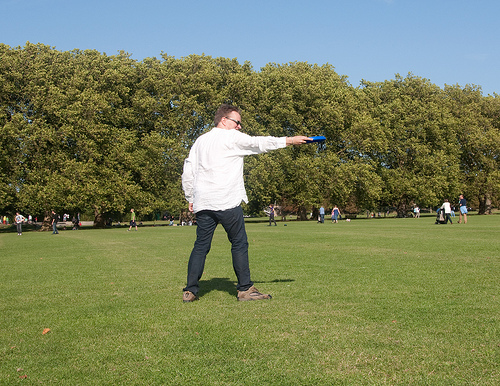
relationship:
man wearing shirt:
[165, 83, 329, 302] [180, 126, 288, 215]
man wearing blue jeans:
[165, 83, 329, 302] [178, 198, 262, 291]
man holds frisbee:
[180, 102, 315, 304] [302, 132, 327, 145]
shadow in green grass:
[190, 261, 293, 299] [0, 209, 499, 385]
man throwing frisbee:
[180, 102, 315, 304] [302, 132, 327, 145]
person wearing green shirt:
[129, 206, 139, 229] [129, 211, 138, 222]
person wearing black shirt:
[49, 209, 59, 230] [51, 214, 59, 224]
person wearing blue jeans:
[49, 209, 59, 230] [48, 223, 61, 236]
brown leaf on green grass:
[39, 328, 53, 337] [1, 209, 499, 385]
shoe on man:
[179, 286, 273, 303] [180, 102, 315, 304]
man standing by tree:
[180, 102, 315, 304] [0, 36, 499, 220]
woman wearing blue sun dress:
[332, 206, 342, 223] [336, 209, 338, 218]